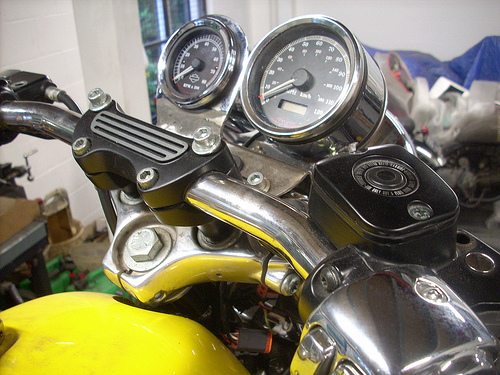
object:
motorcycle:
[1, 14, 498, 374]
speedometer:
[238, 15, 366, 142]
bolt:
[124, 228, 165, 263]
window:
[136, 0, 210, 126]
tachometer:
[157, 14, 239, 110]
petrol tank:
[0, 290, 248, 375]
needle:
[258, 79, 294, 98]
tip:
[257, 95, 262, 99]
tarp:
[362, 35, 500, 89]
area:
[361, 37, 499, 229]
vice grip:
[0, 162, 13, 172]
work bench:
[0, 221, 53, 297]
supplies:
[20, 254, 77, 296]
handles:
[286, 264, 500, 375]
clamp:
[69, 88, 241, 227]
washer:
[121, 227, 172, 270]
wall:
[0, 0, 102, 227]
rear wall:
[294, 1, 498, 61]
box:
[306, 144, 460, 266]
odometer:
[277, 98, 309, 116]